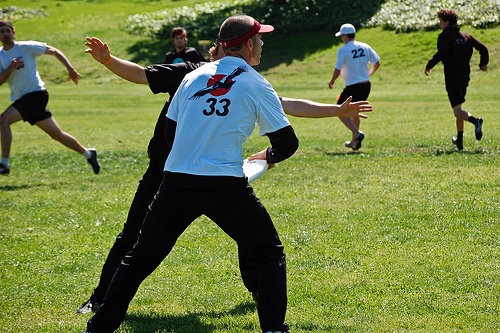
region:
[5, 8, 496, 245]
Competitors in frisbee contest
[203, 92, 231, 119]
Black 33 on t-shirt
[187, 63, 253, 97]
Bird team logo on t-shirt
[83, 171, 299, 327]
Black athletic pants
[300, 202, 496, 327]
Green grass playing field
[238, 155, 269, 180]
White frisbee held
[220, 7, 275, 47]
Red visor for shade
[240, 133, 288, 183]
Right hand holding frisbee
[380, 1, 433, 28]
White flowers on grassy knoll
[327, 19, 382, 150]
Player 22 running route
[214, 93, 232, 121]
black number on white shirt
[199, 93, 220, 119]
black number on white shirt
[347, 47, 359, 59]
black number on white shirt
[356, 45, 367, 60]
black number on white shirt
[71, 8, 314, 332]
person in a field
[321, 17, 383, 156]
person in a field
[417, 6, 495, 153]
person in a field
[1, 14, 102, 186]
person in a field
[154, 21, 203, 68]
person in a field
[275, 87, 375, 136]
arm of a person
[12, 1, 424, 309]
the people are playing frisbee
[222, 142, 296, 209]
the frisbee is white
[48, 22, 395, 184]
the man`s arms are open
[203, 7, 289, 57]
the man is wearing a visor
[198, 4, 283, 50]
the visor is maroon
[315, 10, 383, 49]
the man is wearing a baseball hat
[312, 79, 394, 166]
the man is wearing shorts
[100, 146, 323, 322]
the pants are black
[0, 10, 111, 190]
the man is running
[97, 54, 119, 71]
the man is wearing an orange bracelet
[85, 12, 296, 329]
Man playing in the park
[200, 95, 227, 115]
Number 33 on the man's shirt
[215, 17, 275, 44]
Man has a red visor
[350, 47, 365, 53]
The number 22 on a man's shirt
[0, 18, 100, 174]
A man running in the park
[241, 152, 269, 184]
MAn has a frisbee in his hand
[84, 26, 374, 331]
A player blocking the man from throwing frisbee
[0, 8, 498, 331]
Six men playing on the field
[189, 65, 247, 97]
An eagle with a red circle on a shirt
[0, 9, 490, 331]
Three men with white shirts and three with black shirts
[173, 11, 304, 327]
man playing with a white frisbee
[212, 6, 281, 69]
red visor on a man's head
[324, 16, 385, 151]
person wearing a white ballcap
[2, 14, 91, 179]
man in white shirt running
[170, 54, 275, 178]
white shirt with logo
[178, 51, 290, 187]
white shirt with the number 33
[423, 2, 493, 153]
person in dark clothes running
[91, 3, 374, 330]
frisbee player being blocked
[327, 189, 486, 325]
patch of green grass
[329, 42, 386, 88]
number twenty two on a white shirt